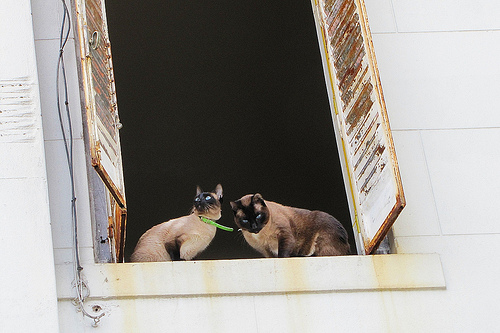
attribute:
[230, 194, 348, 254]
cat — down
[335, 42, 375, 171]
shutters — rusted, open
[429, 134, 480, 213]
wall — white